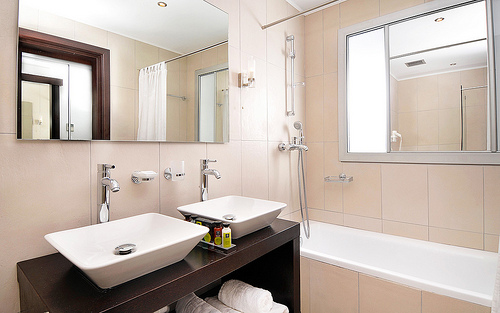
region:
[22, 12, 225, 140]
this is a mirror on the wall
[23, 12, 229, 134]
the mirror is clear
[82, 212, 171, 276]
this is a sink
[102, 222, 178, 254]
the sink is white in color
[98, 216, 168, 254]
the sink is clean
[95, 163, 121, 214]
the tap is closed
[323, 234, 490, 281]
this is a bath tab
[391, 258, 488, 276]
the sink is white in color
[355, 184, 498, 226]
the wall is tiled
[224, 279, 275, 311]
towels are behind the sink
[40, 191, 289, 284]
two square white sinks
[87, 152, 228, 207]
modern faucets over sinks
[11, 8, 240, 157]
mirror on wall over sink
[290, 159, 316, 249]
hose on shower head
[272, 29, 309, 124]
grab bar on wall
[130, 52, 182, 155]
white shower curtain on rod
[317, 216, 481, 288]
white tub surrounded by pink tile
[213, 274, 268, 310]
rolled up white towel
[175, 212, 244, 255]
toiletries in between sinks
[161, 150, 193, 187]
cup holder on wall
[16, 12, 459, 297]
Picture of a bathroom.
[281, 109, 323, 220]
Silver hand held shower sprayer.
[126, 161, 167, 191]
A white bar of soap.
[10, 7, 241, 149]
A large square mirror on the left.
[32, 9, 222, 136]
Reflection in left side mirror of the bathroom.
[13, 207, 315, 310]
Bathroom vanity with two sinks.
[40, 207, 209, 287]
White square sink on left side of vanity.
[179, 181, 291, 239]
White square sink on right side of vanity.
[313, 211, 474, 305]
A white bathtub.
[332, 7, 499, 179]
Large mirror inside shower stall.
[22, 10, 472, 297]
clean and modern bathroom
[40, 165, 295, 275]
two white sinks on one counter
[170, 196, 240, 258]
toiletries on tray between sinks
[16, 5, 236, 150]
mirror reflecting shower curtain and doorway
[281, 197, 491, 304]
white tub against the far wall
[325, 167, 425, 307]
pink tiles on wall and tub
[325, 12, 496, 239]
framed mirror on top of tub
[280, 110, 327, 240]
shower head and metal tubing on wall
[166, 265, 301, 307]
rolled towels in a stack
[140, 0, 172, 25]
round light fixture in ceiling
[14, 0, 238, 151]
the bathroom has a mirror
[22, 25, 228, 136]
the mirror has a reflection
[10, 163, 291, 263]
the bathroom has two sinks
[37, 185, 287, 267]
the sinks are white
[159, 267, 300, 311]
there are towels under the sinks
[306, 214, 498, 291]
the bathtub is white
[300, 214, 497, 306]
the bathtub is clean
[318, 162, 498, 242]
the wall is tile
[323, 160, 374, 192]
soap dish on tile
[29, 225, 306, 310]
the sink cabinet is brown